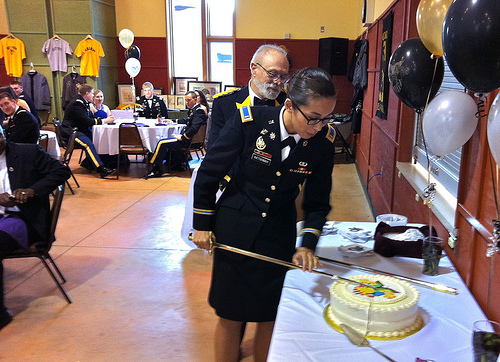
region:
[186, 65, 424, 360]
Woman cutting a cake with a sword.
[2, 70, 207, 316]
People sitting at tables.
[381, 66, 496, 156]
Black and white balloons.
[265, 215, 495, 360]
A white tablecloth on the table.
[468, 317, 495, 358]
Dark liquid in a clear glass.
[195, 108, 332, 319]
Woman in a military uniform.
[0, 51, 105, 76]
Tee shirts hanging on a wall.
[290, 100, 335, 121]
Woman wearing black glasses.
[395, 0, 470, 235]
Window with a white frame.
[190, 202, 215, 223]
Stripes on the jacket sleeve.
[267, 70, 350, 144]
A woman wearing glasses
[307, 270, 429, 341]
A white cake being cut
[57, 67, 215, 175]
A table surrounded by guests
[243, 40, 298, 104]
A man looking on as the cake is cut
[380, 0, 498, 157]
Various colored balloons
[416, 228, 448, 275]
A glass holding balloon strings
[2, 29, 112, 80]
Celebratory shirts hanging on the wall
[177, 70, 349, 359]
A woman wearing a crisp military uniform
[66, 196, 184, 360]
A shiny portion of floor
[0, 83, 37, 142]
Two men watching the cake be cut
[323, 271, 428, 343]
white and yellow frosted cake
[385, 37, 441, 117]
black helium filled balloon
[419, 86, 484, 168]
white helium filled balloon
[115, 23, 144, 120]
table centerpiece made of bouquet of helium filled balloons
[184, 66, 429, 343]
woman using sword to cut cake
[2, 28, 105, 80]
three jerseys hanging on wall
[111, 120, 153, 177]
black chair at table with white tablecloth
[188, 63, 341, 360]
dark haired woman in military style dress uniform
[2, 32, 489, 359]
group of military personnel having party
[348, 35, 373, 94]
black backpack hanging on the wall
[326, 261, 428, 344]
a special cake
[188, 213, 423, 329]
cutting the cake with a sword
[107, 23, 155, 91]
judging from the balloons, someone is having a birthday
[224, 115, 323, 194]
she is a decorated officer in the military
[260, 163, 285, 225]
the buttons on her jacket are gold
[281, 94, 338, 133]
the lady is wearing glasses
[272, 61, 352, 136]
she has her hair all pulled back in a bun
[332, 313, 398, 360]
the cake server is silver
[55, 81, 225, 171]
all the men are in uniform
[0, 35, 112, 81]
two yellow shirts are on the wall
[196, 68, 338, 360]
a woman in her military White Dress uniform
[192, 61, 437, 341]
woman using a sword to cut into a cake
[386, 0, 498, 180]
gold, black, and white balloons over the cake table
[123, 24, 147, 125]
white and black balloons over a dining table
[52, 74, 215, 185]
men in their military dress uniforms sit at a dining table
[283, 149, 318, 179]
the woman's military medals are displayed on her chest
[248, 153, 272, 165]
the woman's name plate is on her right side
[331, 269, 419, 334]
a white cake decorated for the US Army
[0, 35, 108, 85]
yellow and gray t-shirts hang on the wall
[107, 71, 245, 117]
framed photos and documents are on display near the window